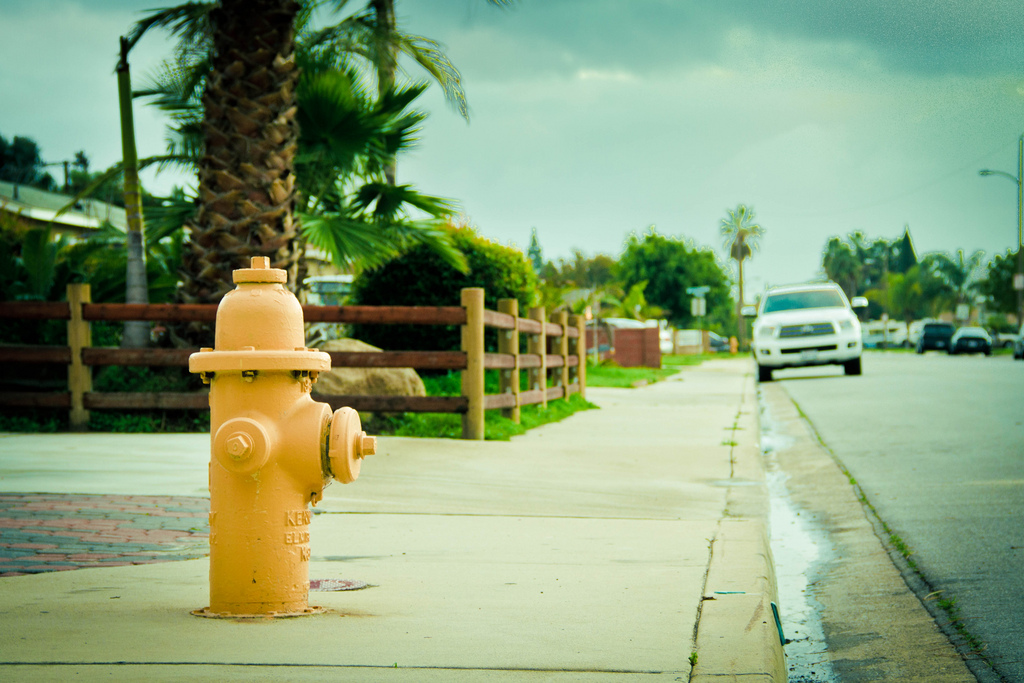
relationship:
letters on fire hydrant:
[276, 504, 315, 543] [166, 225, 385, 632]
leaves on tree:
[287, 212, 441, 269] [153, 13, 339, 357]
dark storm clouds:
[698, 209, 917, 233] [518, 103, 884, 143]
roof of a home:
[61, 203, 88, 216] [2, 252, 149, 363]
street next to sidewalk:
[758, 323, 992, 669] [607, 335, 768, 675]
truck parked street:
[745, 271, 869, 378] [831, 361, 992, 573]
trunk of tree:
[143, 64, 375, 398] [110, 13, 480, 402]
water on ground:
[748, 500, 852, 683] [805, 435, 970, 634]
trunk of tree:
[144, 175, 376, 398] [119, 13, 467, 383]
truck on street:
[713, 256, 900, 421] [821, 372, 992, 632]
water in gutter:
[780, 500, 830, 663] [745, 411, 851, 662]